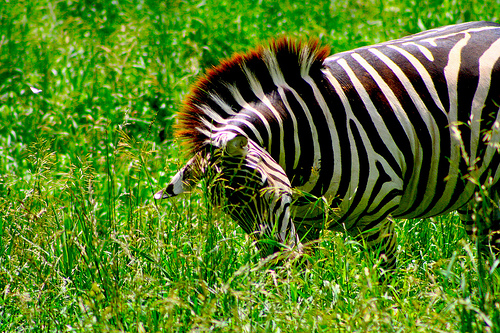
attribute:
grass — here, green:
[2, 0, 500, 332]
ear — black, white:
[152, 151, 204, 200]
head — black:
[153, 71, 309, 270]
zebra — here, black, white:
[152, 21, 498, 292]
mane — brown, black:
[171, 31, 329, 147]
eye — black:
[258, 179, 268, 192]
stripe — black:
[323, 59, 406, 181]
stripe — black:
[429, 28, 500, 220]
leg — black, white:
[356, 215, 396, 291]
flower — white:
[157, 103, 167, 110]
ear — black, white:
[223, 133, 250, 157]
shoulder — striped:
[321, 117, 404, 237]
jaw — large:
[257, 147, 293, 200]